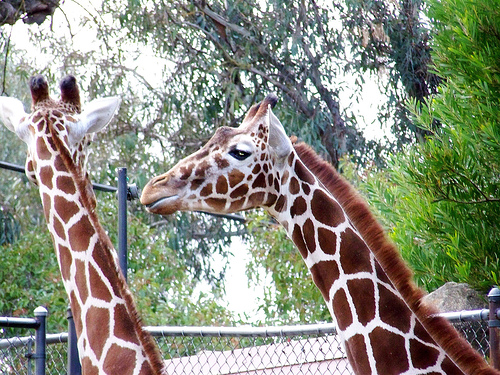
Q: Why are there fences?
A: To keep Giraffes in.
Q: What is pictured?
A: Giraffes.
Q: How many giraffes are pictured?
A: Two.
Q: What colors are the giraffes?
A: Brown and White.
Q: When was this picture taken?
A: Daytime.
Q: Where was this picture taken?
A: A zoo.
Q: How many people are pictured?
A: None.